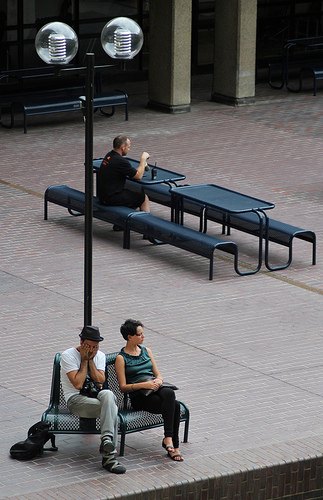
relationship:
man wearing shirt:
[58, 327, 126, 475] [59, 346, 106, 401]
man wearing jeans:
[58, 327, 126, 475] [65, 389, 119, 456]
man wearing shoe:
[58, 327, 126, 475] [100, 438, 116, 457]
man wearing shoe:
[58, 327, 126, 475] [102, 455, 127, 476]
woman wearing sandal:
[115, 318, 182, 462] [167, 453, 184, 464]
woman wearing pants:
[115, 318, 182, 462] [130, 386, 180, 448]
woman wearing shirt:
[115, 318, 182, 462] [119, 346, 155, 383]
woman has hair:
[115, 318, 182, 462] [119, 318, 144, 341]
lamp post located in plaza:
[34, 17, 144, 327] [2, 1, 322, 498]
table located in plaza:
[169, 183, 275, 273] [2, 1, 322, 498]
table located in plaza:
[85, 156, 188, 225] [2, 1, 322, 498]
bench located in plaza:
[126, 211, 239, 282] [2, 1, 322, 498]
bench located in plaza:
[44, 185, 149, 250] [2, 1, 322, 498]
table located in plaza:
[169, 183, 275, 280] [2, 1, 322, 498]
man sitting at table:
[96, 134, 151, 213] [85, 156, 188, 225]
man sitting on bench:
[96, 134, 151, 213] [44, 185, 149, 250]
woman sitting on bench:
[115, 319, 182, 462] [42, 352, 190, 452]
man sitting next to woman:
[58, 327, 126, 475] [115, 318, 182, 462]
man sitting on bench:
[58, 327, 126, 475] [42, 352, 190, 452]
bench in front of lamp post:
[42, 352, 190, 452] [34, 17, 144, 327]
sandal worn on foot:
[167, 453, 184, 464] [162, 439, 176, 454]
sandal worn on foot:
[167, 453, 184, 464] [168, 448, 184, 463]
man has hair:
[96, 134, 151, 213] [111, 135, 130, 149]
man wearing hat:
[58, 327, 126, 475] [79, 327, 104, 343]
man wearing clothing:
[96, 134, 151, 213] [97, 151, 146, 209]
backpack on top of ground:
[9, 418, 58, 461] [0, 68, 322, 499]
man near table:
[96, 134, 151, 213] [85, 156, 188, 225]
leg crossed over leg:
[98, 391, 119, 454] [67, 395, 102, 419]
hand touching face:
[78, 342, 90, 360] [81, 341, 98, 359]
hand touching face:
[89, 347, 98, 361] [81, 341, 98, 359]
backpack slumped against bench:
[9, 418, 58, 461] [42, 352, 190, 452]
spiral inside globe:
[113, 29, 132, 56] [100, 16, 144, 62]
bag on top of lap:
[136, 380, 178, 397] [130, 385, 174, 410]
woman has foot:
[115, 318, 182, 462] [162, 439, 176, 454]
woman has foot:
[115, 318, 182, 462] [168, 448, 184, 463]